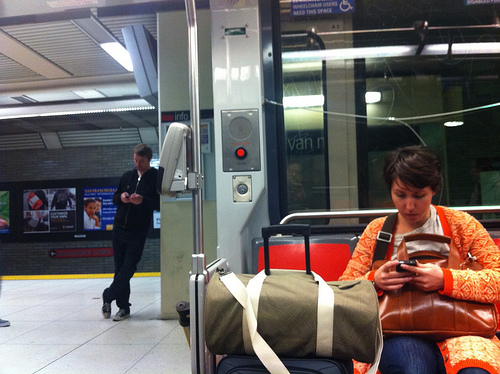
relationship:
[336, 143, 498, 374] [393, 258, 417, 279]
woman holding cellphone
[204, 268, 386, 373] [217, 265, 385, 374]
dufflebag has straps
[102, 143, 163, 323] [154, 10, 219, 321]
man leaning against wall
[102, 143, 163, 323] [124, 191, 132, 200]
man holding cellphone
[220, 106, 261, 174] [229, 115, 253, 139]
cover over speaker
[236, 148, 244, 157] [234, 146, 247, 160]
button has trim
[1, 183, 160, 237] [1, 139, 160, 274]
advertisements along wall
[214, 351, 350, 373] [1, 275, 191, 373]
suitcase standing on ground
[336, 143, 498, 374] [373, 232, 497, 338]
woman holding purse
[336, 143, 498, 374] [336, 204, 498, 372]
woman wearing sweater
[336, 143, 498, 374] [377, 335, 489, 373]
woman wearing jeans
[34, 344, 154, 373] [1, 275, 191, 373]
tile on top of ground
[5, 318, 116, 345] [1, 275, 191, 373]
tile on top of ground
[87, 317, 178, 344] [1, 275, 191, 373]
tile on top of ground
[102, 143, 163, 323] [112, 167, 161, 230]
man wearing jacket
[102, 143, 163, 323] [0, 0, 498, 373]
man waiting at station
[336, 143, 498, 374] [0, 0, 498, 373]
woman waiting at station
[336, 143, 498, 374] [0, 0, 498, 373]
woman inside of station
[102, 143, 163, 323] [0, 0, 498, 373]
man inside of station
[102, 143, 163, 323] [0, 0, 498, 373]
man waiting in station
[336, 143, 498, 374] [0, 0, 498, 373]
woman waiting in station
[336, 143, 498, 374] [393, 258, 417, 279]
woman using cellphone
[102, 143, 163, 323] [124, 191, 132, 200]
man using cellphone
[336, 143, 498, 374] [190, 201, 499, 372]
woman sitting on bench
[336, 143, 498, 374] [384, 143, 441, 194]
woman has hair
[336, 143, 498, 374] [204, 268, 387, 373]
woman sitting with dufflebag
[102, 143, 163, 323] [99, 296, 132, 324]
man wearing sneakers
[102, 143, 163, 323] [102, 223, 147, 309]
man wearing pants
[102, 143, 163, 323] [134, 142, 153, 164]
man has hair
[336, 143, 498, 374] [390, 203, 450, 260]
woman wearing shirt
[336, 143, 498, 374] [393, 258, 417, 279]
woman looking at cellphone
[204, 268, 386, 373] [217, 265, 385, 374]
dufflebag with straps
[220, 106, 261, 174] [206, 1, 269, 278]
cover on side of pillar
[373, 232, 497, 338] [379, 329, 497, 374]
purse on top of lap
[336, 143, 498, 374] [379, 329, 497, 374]
woman has lap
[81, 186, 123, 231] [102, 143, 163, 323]
billboard behind man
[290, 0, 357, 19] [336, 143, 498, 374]
handicap sign above woman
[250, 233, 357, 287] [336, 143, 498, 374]
seat next to woman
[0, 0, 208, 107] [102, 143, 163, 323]
ceiling above man